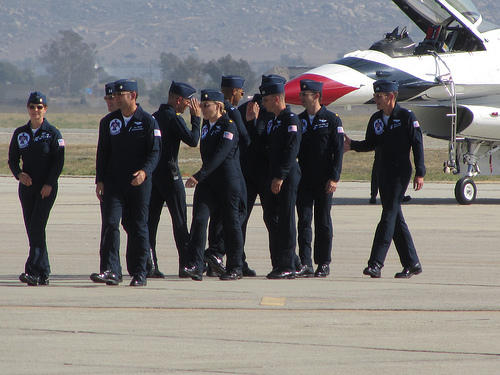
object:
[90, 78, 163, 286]
officer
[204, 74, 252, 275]
people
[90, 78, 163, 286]
outfit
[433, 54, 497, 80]
plane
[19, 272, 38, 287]
shoe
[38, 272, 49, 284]
shoe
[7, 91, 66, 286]
woman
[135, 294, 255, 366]
floor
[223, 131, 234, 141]
patch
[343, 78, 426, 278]
officer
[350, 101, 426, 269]
uniform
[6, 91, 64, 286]
officer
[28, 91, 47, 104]
hat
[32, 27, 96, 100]
tree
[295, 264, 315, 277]
shoes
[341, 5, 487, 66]
cockpit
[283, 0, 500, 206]
jet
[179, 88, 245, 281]
person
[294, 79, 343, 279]
person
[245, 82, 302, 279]
person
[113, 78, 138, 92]
caps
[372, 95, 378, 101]
nose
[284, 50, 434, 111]
logo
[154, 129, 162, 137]
logo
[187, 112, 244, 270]
uniform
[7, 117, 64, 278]
uniform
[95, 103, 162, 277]
uniform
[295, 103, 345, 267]
uniform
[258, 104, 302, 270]
uniform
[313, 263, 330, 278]
shoe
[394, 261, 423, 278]
shoe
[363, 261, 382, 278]
shoe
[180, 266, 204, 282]
shoe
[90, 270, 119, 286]
shoe